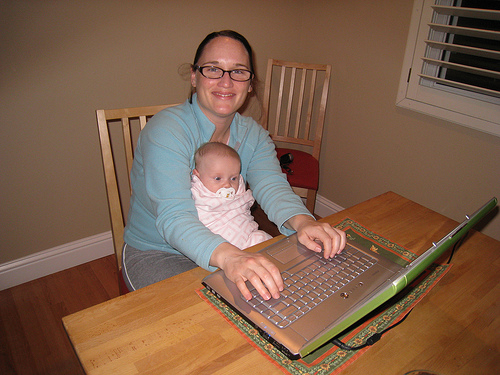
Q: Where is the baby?
A: On the mom's lap.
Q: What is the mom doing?
A: Sitting.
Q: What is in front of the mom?
A: A laptop.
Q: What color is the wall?
A: Beige.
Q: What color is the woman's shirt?
A: Blue.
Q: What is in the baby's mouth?
A: A pacifier.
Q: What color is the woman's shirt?
A: Blue.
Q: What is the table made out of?
A: Wood.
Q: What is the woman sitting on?
A: A wooden chair.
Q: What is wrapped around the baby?
A: A blanket.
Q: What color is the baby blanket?
A: Pink.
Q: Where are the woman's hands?
A: On a silver keyboard.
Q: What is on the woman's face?
A: Eye glasses.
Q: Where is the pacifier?
A: In the baby's mouth.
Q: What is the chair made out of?
A: Wood.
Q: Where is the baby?
A: In the woman's arm.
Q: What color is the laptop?
A: Green and silver.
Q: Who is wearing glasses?
A: The woman.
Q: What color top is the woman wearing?
A: Blue.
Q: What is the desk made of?
A: Wood.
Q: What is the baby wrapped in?
A: A blanket.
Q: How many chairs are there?
A: 2.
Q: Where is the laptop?
A: On a table.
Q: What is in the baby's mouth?
A: A pacifier.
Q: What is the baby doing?
A: Sitting.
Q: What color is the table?
A: Brown.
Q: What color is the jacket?
A: Blue.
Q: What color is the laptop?
A: Silver.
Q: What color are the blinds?
A: White.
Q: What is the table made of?
A: Wood.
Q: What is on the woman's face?
A: GLASSES.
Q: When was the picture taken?
A: Nighttime.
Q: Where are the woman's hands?
A: Computer keyboard.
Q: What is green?
A: Computer housing.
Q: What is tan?
A: Walls.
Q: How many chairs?
A: Two.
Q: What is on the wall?
A: Window.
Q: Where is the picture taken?
A: In the corner of someone's home.